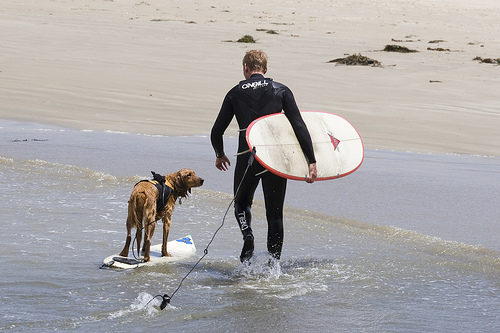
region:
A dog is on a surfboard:
[99, 164, 205, 275]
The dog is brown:
[114, 162, 207, 264]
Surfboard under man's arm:
[244, 102, 368, 191]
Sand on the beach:
[1, 2, 498, 154]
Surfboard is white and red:
[241, 105, 367, 185]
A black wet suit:
[208, 73, 320, 260]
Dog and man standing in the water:
[2, 46, 498, 330]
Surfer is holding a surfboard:
[207, 46, 369, 265]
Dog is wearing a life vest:
[118, 167, 207, 258]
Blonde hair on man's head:
[239, 43, 272, 81]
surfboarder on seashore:
[210, 49, 321, 276]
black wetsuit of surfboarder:
[210, 73, 315, 268]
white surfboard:
[244, 105, 365, 185]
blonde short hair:
[242, 51, 272, 75]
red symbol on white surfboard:
[327, 128, 342, 156]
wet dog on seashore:
[120, 165, 207, 267]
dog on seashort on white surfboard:
[122, 165, 200, 265]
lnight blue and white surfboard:
[104, 229, 202, 277]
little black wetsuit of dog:
[154, 171, 175, 213]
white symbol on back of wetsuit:
[241, 78, 272, 98]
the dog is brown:
[123, 163, 200, 259]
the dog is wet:
[126, 150, 200, 264]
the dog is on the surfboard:
[126, 156, 198, 246]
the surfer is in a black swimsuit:
[218, 61, 340, 247]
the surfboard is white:
[246, 99, 368, 201]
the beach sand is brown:
[83, 13, 184, 96]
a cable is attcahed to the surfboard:
[198, 151, 253, 268]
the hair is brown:
[238, 46, 271, 67]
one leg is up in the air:
[223, 225, 268, 277]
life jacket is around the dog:
[141, 165, 184, 213]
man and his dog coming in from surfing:
[87, 37, 383, 293]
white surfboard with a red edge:
[240, 113, 368, 177]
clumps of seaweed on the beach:
[328, 35, 460, 72]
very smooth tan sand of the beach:
[21, 22, 185, 117]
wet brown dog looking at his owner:
[124, 161, 210, 271]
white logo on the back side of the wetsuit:
[241, 78, 271, 92]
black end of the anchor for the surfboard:
[150, 280, 195, 313]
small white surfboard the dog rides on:
[91, 235, 199, 275]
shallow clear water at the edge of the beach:
[316, 261, 482, 329]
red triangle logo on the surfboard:
[326, 128, 346, 154]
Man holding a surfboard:
[210, 45, 367, 263]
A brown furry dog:
[120, 164, 206, 263]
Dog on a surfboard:
[103, 167, 207, 273]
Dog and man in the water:
[3, 42, 494, 325]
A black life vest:
[143, 163, 178, 219]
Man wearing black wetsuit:
[206, 46, 320, 268]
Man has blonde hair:
[238, 45, 271, 79]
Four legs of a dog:
[116, 217, 177, 266]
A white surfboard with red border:
[242, 106, 366, 184]